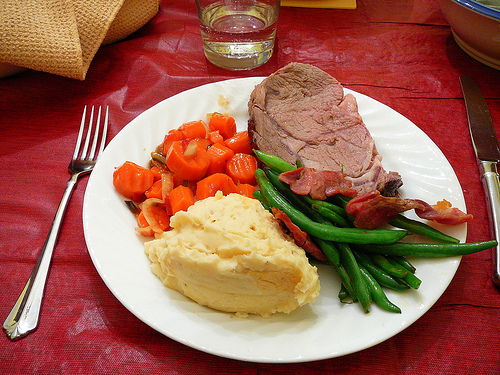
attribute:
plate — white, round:
[392, 111, 462, 190]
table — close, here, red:
[358, 16, 464, 115]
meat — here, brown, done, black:
[257, 66, 369, 162]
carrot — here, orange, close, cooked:
[157, 127, 243, 192]